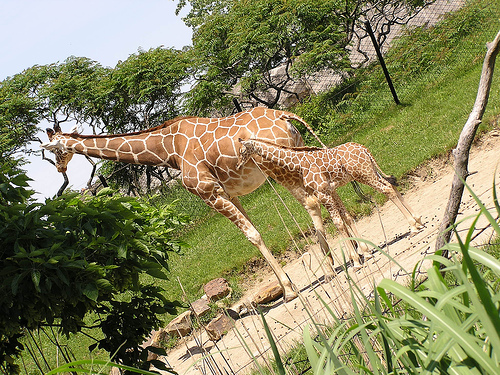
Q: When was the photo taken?
A: Daytime.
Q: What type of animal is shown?
A: Giraffes.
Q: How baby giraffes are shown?
A: One.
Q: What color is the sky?
A: Blue.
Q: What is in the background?
A: Trees.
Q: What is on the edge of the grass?
A: Rocks.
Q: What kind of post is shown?
A: Metal.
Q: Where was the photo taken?
A: Safari.